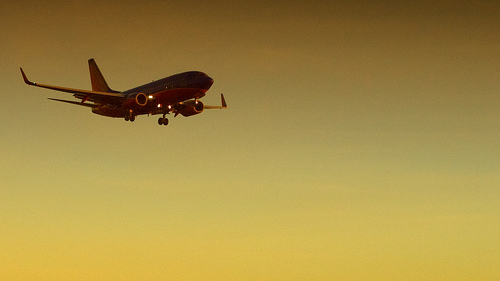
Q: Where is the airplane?
A: In the sky.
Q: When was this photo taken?
A: At dusk.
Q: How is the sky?
A: Clear and yellow.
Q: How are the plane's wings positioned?
A: Out to the side.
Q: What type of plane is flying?
A: Commercial jet.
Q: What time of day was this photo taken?
A: Sunset.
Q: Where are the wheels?
A: Under the plane.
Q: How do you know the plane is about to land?
A: Wheels are out.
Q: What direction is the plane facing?
A: Right.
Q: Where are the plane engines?
A: Between wings and body of the plane.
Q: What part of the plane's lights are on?
A: Bottom.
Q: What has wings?
A: The plane.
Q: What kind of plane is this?
A: A passenger plane.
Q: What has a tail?
A: The plane.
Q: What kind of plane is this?
A: Commercial aircraft.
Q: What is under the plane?
A: Landing gear.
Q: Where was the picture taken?
A: Near airport.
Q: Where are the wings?
A: Attached to the plane.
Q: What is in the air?
A: A plane.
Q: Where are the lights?
A: Under the plane.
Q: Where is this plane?
A: Sky.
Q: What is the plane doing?
A: Flying.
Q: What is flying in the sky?
A: Plane.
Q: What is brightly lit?
A: Lights.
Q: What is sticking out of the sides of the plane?
A: Wings.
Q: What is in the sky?
A: An airplane.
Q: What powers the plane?
A: Jet engines.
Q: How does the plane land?
A: With flaps and landing gear deployed.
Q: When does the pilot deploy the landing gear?
A: Before the final approach.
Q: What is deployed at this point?
A: The landing gear.